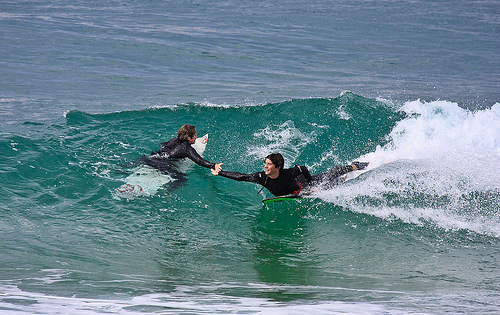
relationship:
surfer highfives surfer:
[215, 154, 367, 196] [120, 125, 223, 200]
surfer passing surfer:
[215, 154, 367, 196] [120, 125, 223, 200]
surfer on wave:
[215, 154, 367, 196] [5, 92, 495, 222]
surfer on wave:
[120, 125, 223, 200] [5, 92, 495, 222]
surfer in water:
[215, 154, 367, 196] [1, 2, 497, 311]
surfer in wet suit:
[120, 125, 223, 200] [128, 138, 214, 190]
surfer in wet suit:
[215, 154, 367, 196] [221, 170, 356, 196]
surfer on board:
[120, 125, 223, 200] [116, 134, 208, 201]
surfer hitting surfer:
[215, 154, 367, 196] [120, 125, 223, 200]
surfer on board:
[215, 154, 367, 196] [263, 196, 305, 206]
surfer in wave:
[215, 154, 367, 196] [5, 92, 495, 222]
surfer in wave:
[120, 125, 223, 200] [5, 92, 495, 222]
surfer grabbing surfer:
[215, 154, 367, 196] [120, 125, 223, 200]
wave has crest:
[5, 92, 495, 222] [56, 91, 396, 120]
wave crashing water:
[5, 92, 495, 222] [1, 2, 497, 315]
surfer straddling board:
[120, 125, 223, 200] [116, 134, 208, 201]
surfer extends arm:
[215, 154, 367, 196] [216, 168, 267, 183]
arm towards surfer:
[216, 168, 267, 183] [120, 125, 223, 200]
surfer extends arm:
[120, 125, 223, 200] [189, 146, 224, 172]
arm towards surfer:
[189, 146, 224, 172] [215, 154, 367, 196]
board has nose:
[116, 134, 208, 201] [195, 131, 209, 154]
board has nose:
[263, 196, 305, 206] [262, 198, 276, 205]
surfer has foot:
[215, 154, 367, 196] [327, 161, 367, 175]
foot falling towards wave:
[327, 161, 367, 175] [5, 92, 495, 222]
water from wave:
[1, 2, 497, 315] [5, 92, 495, 222]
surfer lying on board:
[120, 125, 223, 200] [116, 134, 208, 201]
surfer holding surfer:
[215, 154, 367, 196] [120, 125, 223, 200]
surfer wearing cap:
[215, 154, 367, 196] [267, 153, 284, 172]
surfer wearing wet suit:
[215, 154, 367, 196] [221, 170, 356, 196]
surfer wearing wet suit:
[120, 125, 223, 200] [128, 138, 214, 190]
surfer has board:
[215, 154, 367, 196] [263, 196, 305, 206]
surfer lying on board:
[215, 154, 367, 196] [263, 196, 305, 206]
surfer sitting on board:
[120, 125, 223, 200] [116, 134, 208, 201]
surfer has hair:
[120, 125, 223, 200] [179, 124, 197, 141]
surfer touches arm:
[215, 154, 367, 196] [189, 146, 224, 172]